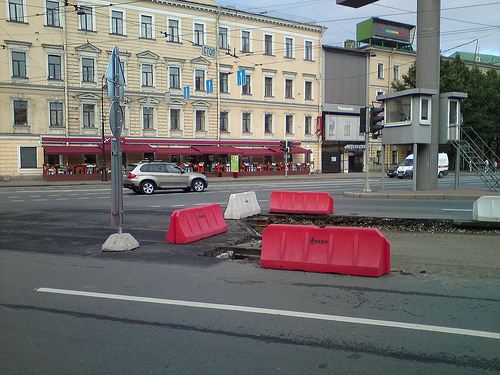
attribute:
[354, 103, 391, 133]
traffic stop — electronic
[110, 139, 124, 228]
sign —  a set,  street's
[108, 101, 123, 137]
sign —  street's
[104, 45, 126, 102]
sign —  street's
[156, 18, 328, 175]
wall —  cream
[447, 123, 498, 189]
stairs — metal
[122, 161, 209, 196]
car — silver, moving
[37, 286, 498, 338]
lane marker —  white , a line , of lane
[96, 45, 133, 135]
sign —  Two, at top,  silver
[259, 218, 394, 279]
barrier — red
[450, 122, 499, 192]
stairs —  a short set ,  metal framed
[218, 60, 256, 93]
sign — blue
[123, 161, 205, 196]
suv — compact , small , olive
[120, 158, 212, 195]
grey car —  grey 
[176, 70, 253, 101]
flags —  small ,  blue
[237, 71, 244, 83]
emblem —  white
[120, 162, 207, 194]
suv — small, beige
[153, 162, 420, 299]
road barriers —  road's,  red,   plastic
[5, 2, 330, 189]
building — beige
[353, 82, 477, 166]
boxes —  large,  retangle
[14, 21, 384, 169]
beige brick —  beige, of building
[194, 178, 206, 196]
wheel — black, round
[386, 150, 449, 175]
white van — behind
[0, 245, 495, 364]
road —  tarmacked 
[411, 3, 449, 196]
pole — Very thick,  round , between two small buildings 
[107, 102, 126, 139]
sign —  silver,  round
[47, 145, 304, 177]
lobby —  burgandy